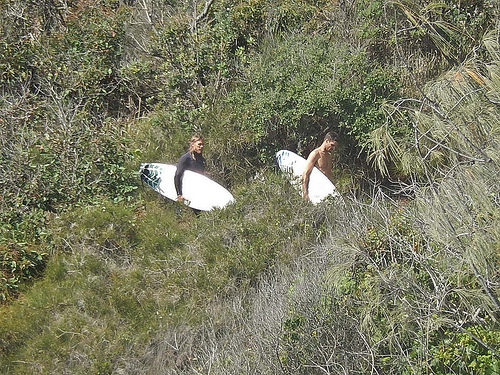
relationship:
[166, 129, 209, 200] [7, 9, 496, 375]
man in bushes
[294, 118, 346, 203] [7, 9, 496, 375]
man in bushes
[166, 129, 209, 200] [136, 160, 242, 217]
man holding surfboard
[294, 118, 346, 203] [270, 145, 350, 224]
man holding surfboard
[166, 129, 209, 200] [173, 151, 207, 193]
man wears wetsuit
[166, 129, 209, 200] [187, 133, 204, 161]
man has hair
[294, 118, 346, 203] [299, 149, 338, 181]
man not wearing shirt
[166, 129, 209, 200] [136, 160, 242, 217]
man walk with surfboard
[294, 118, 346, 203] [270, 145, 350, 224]
man walks with surfboard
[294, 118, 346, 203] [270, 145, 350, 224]
man holds surfboard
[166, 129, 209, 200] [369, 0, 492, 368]
man face right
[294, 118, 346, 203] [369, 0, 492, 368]
man face right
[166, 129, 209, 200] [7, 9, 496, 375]
man walks on dense undergrowth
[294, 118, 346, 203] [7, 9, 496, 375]
man walks through dense undergrowth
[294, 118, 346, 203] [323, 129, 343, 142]
man has short hair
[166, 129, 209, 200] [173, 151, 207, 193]
surfer in wetsuit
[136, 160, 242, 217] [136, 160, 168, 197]
surfboard pas pattern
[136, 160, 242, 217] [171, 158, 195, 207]
surfboard under arm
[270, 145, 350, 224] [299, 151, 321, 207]
surfboard under arm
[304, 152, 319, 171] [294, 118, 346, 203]
bicep of man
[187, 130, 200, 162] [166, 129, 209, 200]
hair of man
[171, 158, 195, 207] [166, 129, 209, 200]
right arm of man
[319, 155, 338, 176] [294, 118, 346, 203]
chest of man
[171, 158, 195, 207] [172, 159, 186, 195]
arm on right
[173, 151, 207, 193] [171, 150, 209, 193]
man i wearing a wetsuit